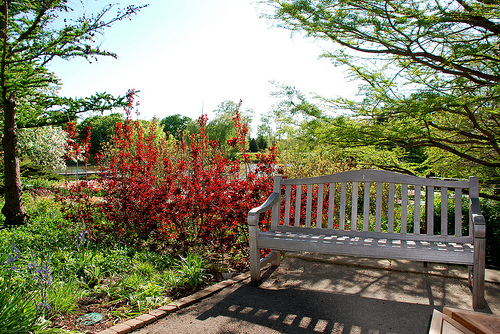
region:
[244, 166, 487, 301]
a white wood park bench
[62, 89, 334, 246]
a red flowering bush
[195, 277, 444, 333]
shadow of a park bench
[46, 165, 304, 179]
a body of water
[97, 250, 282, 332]
a line of paver bricks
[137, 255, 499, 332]
a paved patio area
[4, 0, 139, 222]
a large green tree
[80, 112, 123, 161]
a large green tree in distance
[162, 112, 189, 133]
a large green tree in distance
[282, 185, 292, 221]
a wooden slat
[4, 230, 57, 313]
a few blue flowers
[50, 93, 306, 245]
a large blossoming plant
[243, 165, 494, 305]
a light colored bench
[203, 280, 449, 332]
a shadow on the ground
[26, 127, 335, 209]
a pond surrounded by plants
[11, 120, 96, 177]
a tree covered in blossoms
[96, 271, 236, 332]
a row of bricks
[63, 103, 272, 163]
a variety of trees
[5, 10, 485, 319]
a park like setting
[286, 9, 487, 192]
a few long tree branches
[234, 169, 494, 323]
a wooden bench at a park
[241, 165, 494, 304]
a grey bench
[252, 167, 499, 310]
an empty bench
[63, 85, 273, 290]
a bush of red flowers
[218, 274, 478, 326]
the shadow of a bench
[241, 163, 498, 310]
a bench on a dirt patch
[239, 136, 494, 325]
a bench in the middle of a park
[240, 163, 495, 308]
a bench near some trees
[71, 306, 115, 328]
a water pipe system cover in the dirt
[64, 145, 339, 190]
a lake behind the flowers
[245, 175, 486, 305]
Wooden bench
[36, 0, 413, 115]
Cloudless blue sky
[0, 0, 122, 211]
A leafy tree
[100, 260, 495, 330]
Ground paved with concrete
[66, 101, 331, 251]
Tall plants with red flowers or leaves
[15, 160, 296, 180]
Small body of water behind plants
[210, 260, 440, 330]
Shadow of wooden bench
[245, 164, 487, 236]
Curved back and armrests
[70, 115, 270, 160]
Many far away trees in background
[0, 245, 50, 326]
A few short plants with purple flowers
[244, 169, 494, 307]
a white bench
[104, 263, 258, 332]
brick edging a concrete pad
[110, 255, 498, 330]
a concrete pad under a white bench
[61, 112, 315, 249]
a red flowering plant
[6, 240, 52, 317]
blue flowers in the grass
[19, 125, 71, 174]
a white flowering tree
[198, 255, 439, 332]
the shadow of a bench on the concrete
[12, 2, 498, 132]
a pale blue sky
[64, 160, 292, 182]
water behind the plants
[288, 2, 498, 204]
tree branches next to a bench